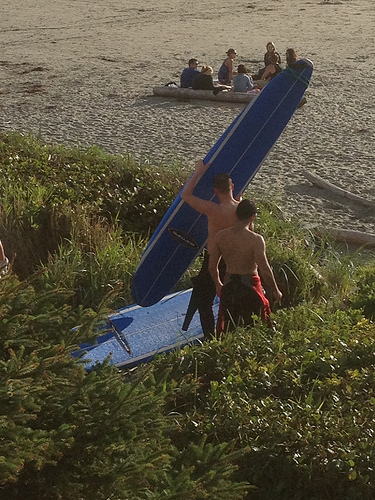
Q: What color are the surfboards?
A: Blue.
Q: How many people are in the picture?
A: Nine.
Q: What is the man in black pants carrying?
A: A surfboard.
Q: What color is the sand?
A: Brown.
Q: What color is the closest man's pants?
A: Black and red.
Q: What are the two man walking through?
A: Vegetation.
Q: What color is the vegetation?
A: Green.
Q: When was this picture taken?
A: Daytime.